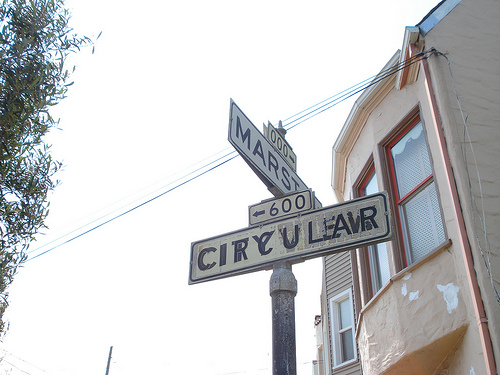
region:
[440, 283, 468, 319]
Chipped white paint on the yellow building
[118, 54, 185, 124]
The sky looks extremely bright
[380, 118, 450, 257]
A red framed window on the yellow building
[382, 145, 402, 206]
A red trim around the window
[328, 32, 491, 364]
A yellow building by the street signs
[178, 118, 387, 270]
White street signs by the building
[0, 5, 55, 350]
A green tree to the left of the street signs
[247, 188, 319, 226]
This small white sign says "600"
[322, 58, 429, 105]
Black telephone wires running from the building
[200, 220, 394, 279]
This white street sign says "Circular"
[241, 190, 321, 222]
black lettered 600 sign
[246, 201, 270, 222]
black arrow pointing left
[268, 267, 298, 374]
wide gray metal pole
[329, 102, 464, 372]
red trimmed bay windows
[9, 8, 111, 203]
small leafed tree branches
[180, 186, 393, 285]
black lettered circular sign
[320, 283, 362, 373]
rectangular shaped window with white trim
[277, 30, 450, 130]
black wires extending from house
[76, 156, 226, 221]
telephones wires against cloudless sky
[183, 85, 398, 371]
several signs on top of gray metal post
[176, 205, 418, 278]
Street sign with letters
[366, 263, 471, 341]
Chipped painting wall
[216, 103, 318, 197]
Sign reading MARST st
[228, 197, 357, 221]
Small sign says 600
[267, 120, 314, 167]
Small sign says 000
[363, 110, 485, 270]
Building with red windows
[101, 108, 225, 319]
Sky with power line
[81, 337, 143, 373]
Top of power line pole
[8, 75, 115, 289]
Tree is green with leaves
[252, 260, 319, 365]
Old sign post pole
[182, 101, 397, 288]
Street signs on a corner.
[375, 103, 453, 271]
A window on the second floor of a building.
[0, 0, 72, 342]
Leaves on a tree.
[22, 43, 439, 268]
Wires going from the building towards the tree.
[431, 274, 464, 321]
Paint that has peeled.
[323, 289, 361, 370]
White framed window.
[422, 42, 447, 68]
Wires connected to the building.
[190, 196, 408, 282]
One street name over another name on sign.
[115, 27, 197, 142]
White sky.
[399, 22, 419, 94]
Gutter on building.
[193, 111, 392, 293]
signs on a pole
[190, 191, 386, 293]
a black and white sign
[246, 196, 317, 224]
a sign with numbers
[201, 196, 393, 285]
a black and white sign with writing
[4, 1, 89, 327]
a leafy tree by wire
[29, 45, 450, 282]
a wire over the signs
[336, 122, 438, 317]
a window in a building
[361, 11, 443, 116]
the edge of a roof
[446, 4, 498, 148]
a concrete wall of building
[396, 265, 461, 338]
paint peeling off window